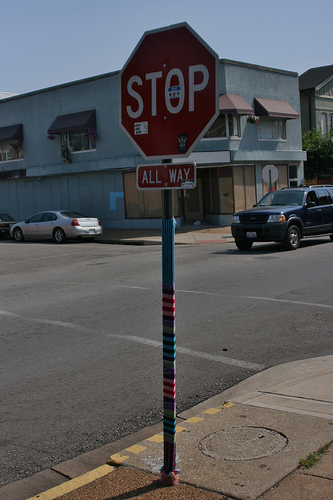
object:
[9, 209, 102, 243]
car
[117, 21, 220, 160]
stop sign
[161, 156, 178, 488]
post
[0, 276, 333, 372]
crosswalk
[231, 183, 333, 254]
suv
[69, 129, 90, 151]
window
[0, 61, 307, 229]
building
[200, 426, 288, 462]
cap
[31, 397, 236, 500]
curb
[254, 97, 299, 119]
awning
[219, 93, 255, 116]
awning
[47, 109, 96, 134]
awning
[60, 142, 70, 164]
plants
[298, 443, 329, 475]
weeds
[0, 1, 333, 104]
sky